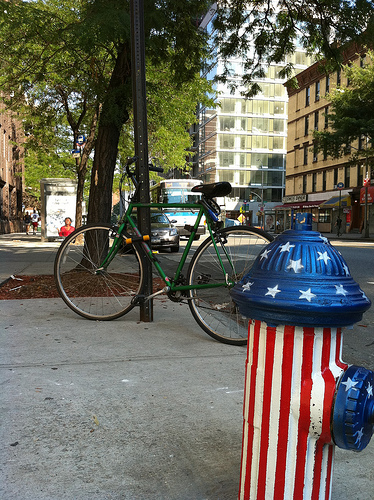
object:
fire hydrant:
[227, 212, 374, 499]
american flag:
[228, 212, 373, 499]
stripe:
[273, 324, 296, 499]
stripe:
[249, 322, 269, 499]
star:
[297, 288, 317, 302]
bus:
[151, 178, 208, 241]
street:
[121, 236, 373, 373]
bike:
[53, 153, 276, 346]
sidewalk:
[0, 232, 374, 499]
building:
[195, 0, 337, 225]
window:
[218, 134, 235, 150]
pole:
[128, 0, 153, 323]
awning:
[320, 194, 352, 210]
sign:
[46, 194, 76, 240]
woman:
[57, 217, 75, 237]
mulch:
[0, 273, 168, 300]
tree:
[57, 0, 156, 275]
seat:
[190, 180, 232, 196]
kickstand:
[177, 293, 217, 302]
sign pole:
[41, 180, 47, 243]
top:
[230, 212, 372, 327]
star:
[278, 240, 296, 254]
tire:
[53, 222, 148, 321]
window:
[249, 135, 269, 150]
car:
[113, 212, 180, 257]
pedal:
[130, 293, 148, 307]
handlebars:
[125, 157, 165, 173]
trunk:
[80, 41, 131, 265]